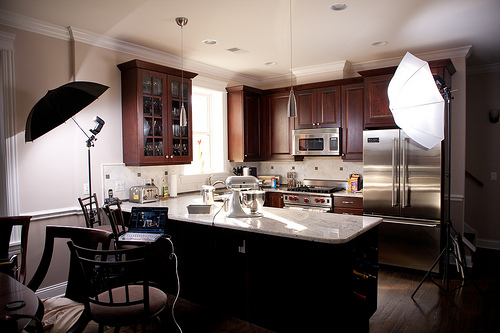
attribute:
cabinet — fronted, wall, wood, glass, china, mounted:
[116, 54, 201, 168]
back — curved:
[71, 239, 155, 319]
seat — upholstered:
[90, 278, 170, 323]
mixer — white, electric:
[221, 172, 268, 220]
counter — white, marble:
[110, 190, 385, 244]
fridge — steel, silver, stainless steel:
[358, 126, 451, 276]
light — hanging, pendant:
[175, 13, 195, 127]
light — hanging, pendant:
[284, 1, 304, 117]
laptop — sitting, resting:
[119, 204, 173, 244]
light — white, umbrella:
[19, 89, 229, 209]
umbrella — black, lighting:
[21, 77, 111, 224]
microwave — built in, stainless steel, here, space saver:
[290, 125, 340, 154]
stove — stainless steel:
[282, 175, 346, 205]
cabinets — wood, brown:
[225, 56, 457, 163]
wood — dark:
[228, 58, 457, 164]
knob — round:
[164, 153, 169, 157]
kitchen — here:
[7, 1, 497, 326]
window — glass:
[144, 76, 164, 153]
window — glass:
[173, 82, 188, 151]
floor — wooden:
[76, 243, 499, 330]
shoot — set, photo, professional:
[8, 1, 495, 331]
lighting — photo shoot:
[386, 51, 475, 309]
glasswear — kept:
[171, 123, 188, 138]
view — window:
[192, 87, 225, 180]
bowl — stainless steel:
[238, 188, 269, 210]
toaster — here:
[127, 182, 161, 204]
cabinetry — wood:
[119, 54, 458, 166]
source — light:
[21, 76, 113, 269]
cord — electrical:
[210, 195, 227, 232]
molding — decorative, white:
[0, 7, 476, 93]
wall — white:
[15, 29, 235, 281]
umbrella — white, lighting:
[387, 47, 483, 299]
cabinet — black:
[241, 245, 338, 322]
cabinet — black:
[341, 229, 383, 317]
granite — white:
[114, 189, 381, 247]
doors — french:
[364, 129, 446, 212]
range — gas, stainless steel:
[284, 175, 354, 208]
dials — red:
[286, 194, 331, 202]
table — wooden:
[3, 267, 43, 328]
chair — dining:
[29, 221, 121, 330]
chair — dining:
[2, 215, 38, 274]